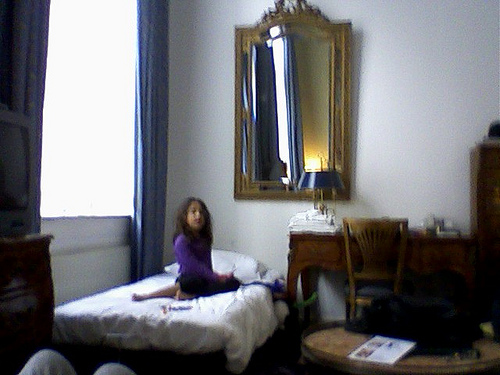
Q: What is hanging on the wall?
A: A mirror.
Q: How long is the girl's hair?
A: Medium-length.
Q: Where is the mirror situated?
A: Hanging on the wall above the bed.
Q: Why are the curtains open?
A: To allow light into the room.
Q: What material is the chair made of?
A: Wood.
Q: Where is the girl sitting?
A: On the bed.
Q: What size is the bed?
A: Twin size.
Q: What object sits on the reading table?
A: A lamp.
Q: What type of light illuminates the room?
A: Sunshine.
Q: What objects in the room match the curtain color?
A: The lamp shade and the chair cushion.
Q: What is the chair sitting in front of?
A: Desk.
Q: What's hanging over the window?
A: Curtains.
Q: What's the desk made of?
A: Wood.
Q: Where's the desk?
A: Along wall.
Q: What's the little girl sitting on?
A: Bed.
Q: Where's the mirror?
A: Hanging.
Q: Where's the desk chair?
A: Front of desk.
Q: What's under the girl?
A: Bed.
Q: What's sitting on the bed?
A: Child.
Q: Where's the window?
A: Behind girl.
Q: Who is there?
A: Little girl.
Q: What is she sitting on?
A: Bed.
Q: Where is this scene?
A: Bedroom.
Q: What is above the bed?
A: Mirror.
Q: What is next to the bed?
A: Dresser.